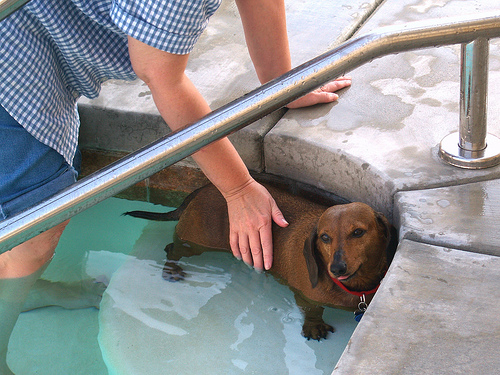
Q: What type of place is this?
A: It is a pavement.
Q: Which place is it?
A: It is a pavement.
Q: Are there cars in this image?
A: No, there are no cars.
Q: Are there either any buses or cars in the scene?
A: No, there are no cars or buses.